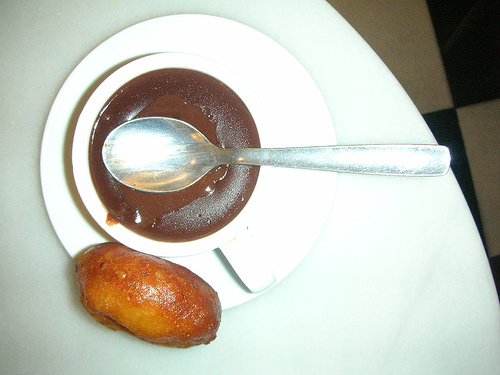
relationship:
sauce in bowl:
[194, 93, 223, 118] [125, 65, 148, 78]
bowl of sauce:
[125, 65, 148, 78] [194, 93, 223, 118]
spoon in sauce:
[93, 102, 477, 188] [194, 93, 223, 118]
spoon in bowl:
[93, 102, 477, 188] [125, 65, 148, 78]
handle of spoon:
[253, 126, 447, 180] [93, 102, 477, 188]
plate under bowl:
[218, 22, 317, 60] [125, 65, 148, 78]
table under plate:
[292, 16, 304, 18] [218, 22, 317, 60]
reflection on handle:
[398, 154, 442, 171] [253, 126, 447, 180]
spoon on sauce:
[93, 102, 477, 188] [194, 93, 223, 118]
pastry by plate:
[68, 242, 198, 329] [218, 22, 317, 60]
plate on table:
[218, 22, 317, 60] [292, 16, 304, 18]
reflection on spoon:
[398, 154, 442, 171] [93, 102, 477, 188]